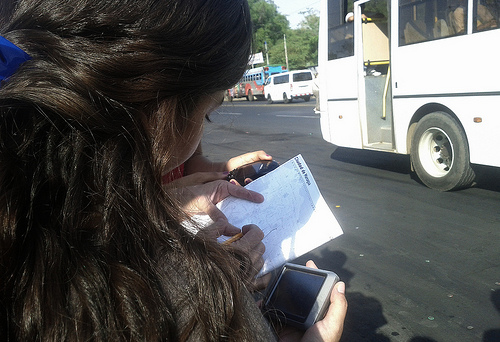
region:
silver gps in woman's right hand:
[262, 245, 346, 337]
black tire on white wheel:
[401, 97, 476, 204]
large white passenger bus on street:
[308, 0, 498, 237]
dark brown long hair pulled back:
[1, 0, 358, 340]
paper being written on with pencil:
[203, 159, 342, 266]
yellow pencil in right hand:
[195, 215, 268, 287]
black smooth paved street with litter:
[352, 171, 417, 266]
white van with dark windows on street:
[261, 71, 313, 103]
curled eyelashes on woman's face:
[199, 110, 216, 126]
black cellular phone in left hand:
[198, 157, 285, 189]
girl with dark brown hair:
[151, 3, 256, 205]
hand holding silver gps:
[269, 254, 364, 336]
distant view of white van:
[263, 73, 320, 104]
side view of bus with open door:
[318, 0, 485, 148]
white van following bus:
[238, 63, 321, 109]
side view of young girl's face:
[141, 15, 251, 200]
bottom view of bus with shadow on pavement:
[315, 81, 442, 203]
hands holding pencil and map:
[205, 150, 370, 273]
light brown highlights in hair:
[28, 7, 113, 147]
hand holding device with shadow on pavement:
[293, 259, 395, 341]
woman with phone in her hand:
[15, 10, 339, 340]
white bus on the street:
[315, 5, 497, 203]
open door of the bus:
[354, 1, 414, 150]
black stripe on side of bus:
[323, 87, 495, 106]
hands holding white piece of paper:
[171, 140, 339, 264]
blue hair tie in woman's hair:
[3, 33, 28, 76]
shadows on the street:
[312, 235, 499, 333]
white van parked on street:
[262, 69, 314, 101]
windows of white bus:
[326, 1, 491, 50]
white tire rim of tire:
[411, 129, 451, 170]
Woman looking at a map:
[1, 0, 349, 340]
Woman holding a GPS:
[1, 0, 349, 341]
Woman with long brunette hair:
[1, 0, 347, 340]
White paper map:
[165, 153, 342, 280]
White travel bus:
[315, 0, 497, 194]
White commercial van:
[261, 68, 316, 103]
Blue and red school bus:
[222, 64, 286, 101]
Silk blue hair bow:
[0, 34, 30, 86]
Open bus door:
[357, 0, 403, 148]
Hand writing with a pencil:
[192, 215, 268, 288]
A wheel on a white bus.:
[410, 111, 479, 191]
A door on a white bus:
[357, 0, 391, 153]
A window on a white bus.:
[325, 0, 352, 60]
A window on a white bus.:
[396, 0, 468, 45]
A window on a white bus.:
[470, 0, 498, 35]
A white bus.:
[315, 0, 498, 190]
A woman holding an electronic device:
[1, 0, 347, 340]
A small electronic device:
[258, 262, 338, 329]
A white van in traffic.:
[263, 69, 313, 101]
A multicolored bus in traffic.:
[222, 64, 287, 101]